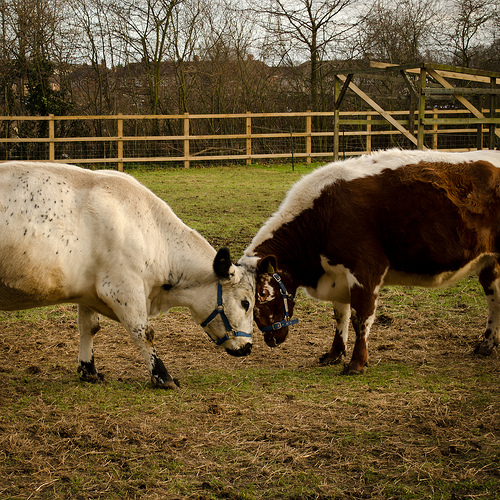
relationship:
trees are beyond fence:
[0, 1, 496, 107] [1, 108, 499, 176]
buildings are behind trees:
[6, 50, 354, 92] [0, 1, 496, 107]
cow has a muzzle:
[240, 139, 500, 374] [256, 264, 298, 336]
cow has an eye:
[240, 139, 500, 374] [254, 287, 268, 299]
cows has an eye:
[0, 158, 259, 390] [237, 295, 250, 313]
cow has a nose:
[240, 139, 500, 374] [261, 329, 277, 348]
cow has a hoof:
[240, 139, 500, 374] [340, 361, 374, 375]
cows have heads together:
[0, 120, 499, 390] [198, 218, 299, 359]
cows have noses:
[0, 120, 499, 390] [232, 330, 278, 355]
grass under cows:
[3, 165, 500, 499] [0, 120, 499, 390]